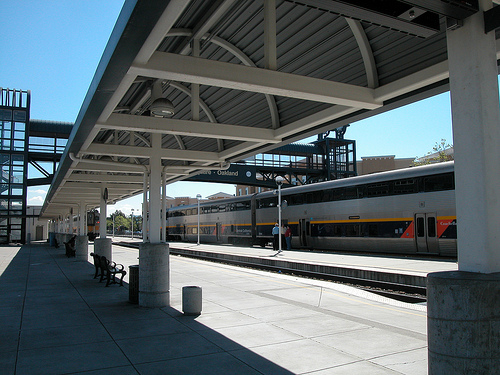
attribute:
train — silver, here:
[142, 148, 469, 264]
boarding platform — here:
[78, 233, 438, 355]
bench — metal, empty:
[86, 251, 135, 290]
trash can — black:
[124, 261, 146, 306]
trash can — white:
[177, 280, 206, 318]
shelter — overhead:
[35, 0, 481, 227]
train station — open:
[2, 2, 496, 370]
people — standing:
[266, 215, 301, 251]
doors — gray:
[410, 208, 439, 257]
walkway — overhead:
[0, 79, 374, 200]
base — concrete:
[132, 233, 175, 319]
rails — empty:
[119, 236, 428, 313]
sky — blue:
[1, 4, 128, 128]